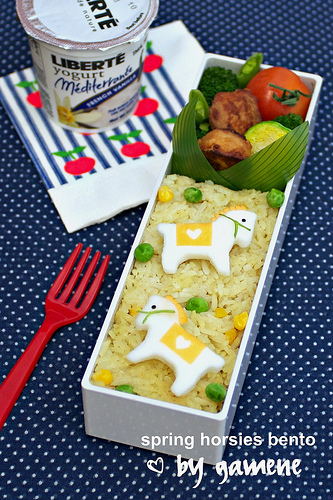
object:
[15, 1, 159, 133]
yogurt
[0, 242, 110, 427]
fork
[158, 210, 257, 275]
candy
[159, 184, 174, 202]
corn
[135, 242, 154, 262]
pea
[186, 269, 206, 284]
rice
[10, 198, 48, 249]
tablecloth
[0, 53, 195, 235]
napkin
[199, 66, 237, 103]
broccoli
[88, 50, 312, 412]
food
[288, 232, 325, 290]
table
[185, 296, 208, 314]
peas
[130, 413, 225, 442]
container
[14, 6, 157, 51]
top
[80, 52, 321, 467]
box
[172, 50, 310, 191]
vegetables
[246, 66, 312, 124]
fruit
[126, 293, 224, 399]
horse